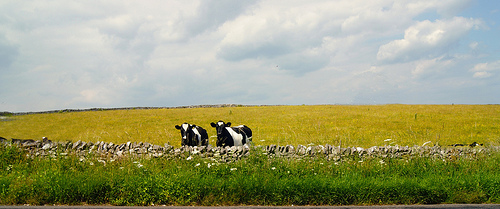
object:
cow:
[209, 120, 253, 149]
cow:
[173, 122, 209, 147]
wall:
[181, 103, 237, 107]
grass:
[0, 157, 499, 203]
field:
[0, 104, 500, 144]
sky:
[0, 1, 500, 104]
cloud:
[0, 2, 493, 106]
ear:
[226, 122, 232, 127]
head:
[210, 120, 232, 135]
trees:
[5, 114, 13, 118]